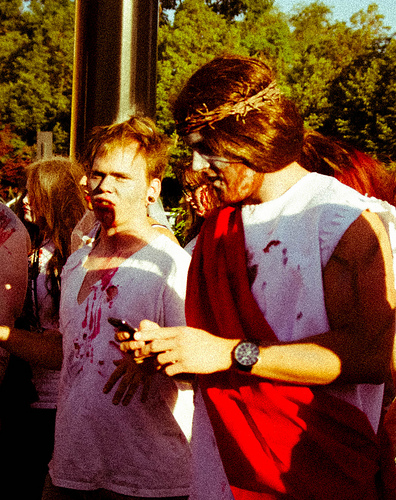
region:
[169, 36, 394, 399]
this is a person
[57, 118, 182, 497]
this is a person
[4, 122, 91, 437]
this is a person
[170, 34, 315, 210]
this is a head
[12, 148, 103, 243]
this is a head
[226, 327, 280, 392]
this is a watch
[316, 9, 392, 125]
this is green vegetation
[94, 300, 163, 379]
this is a mobile phone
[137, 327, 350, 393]
this is a hand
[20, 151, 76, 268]
THIS IS A PERSON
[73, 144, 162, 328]
THIS IS A PERSON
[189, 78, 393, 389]
THIS IS A PERSON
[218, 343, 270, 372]
THIS IS A WATCH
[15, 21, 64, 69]
THESE ARE BIG TREES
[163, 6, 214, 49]
THESE ARE BIG TREES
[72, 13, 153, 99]
THIS IS A POLE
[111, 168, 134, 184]
THIS IS AN EYE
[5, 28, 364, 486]
people covered in fake blood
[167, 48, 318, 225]
man with thorns on head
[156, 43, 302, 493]
man with watch on wrist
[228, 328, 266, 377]
a black and white watch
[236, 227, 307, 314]
blood on a shirt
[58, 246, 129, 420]
blood on a shirt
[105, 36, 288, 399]
a man looking at his cellphone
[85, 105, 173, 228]
a man with a shadow on his chin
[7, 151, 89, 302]
a woman with long hair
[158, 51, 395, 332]
a man dressed as Jesus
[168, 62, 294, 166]
man wearing crowned thorn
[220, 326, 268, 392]
man is wearing watch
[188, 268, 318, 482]
man has on red sash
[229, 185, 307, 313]
man has on blood shirt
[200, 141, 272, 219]
man has blood on face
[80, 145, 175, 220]
man has pierced ear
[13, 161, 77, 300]
woman is wearing white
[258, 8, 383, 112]
trees can be seen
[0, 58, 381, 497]
a group of people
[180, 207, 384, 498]
red sash around the body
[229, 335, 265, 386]
watch around the wrist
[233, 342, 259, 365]
face of the clock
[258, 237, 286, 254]
red spot on the fabric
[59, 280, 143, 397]
red stains on the shirt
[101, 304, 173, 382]
hand cradling a phone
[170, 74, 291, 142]
headband around the head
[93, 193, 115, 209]
mouth is slightly open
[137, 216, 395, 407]
arm is bent at the elbow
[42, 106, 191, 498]
A person is standing up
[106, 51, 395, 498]
A person is standing up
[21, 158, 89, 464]
A person is standing up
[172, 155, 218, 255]
A person is standing up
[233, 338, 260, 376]
A watch used to keep time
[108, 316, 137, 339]
A phone used for calling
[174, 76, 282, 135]
A thing to keep your hair neat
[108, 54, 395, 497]
A person on his phone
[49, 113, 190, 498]
A person with a look on his face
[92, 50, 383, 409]
man holding a phone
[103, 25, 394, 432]
man looking at a phone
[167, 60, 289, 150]
a crown of thorns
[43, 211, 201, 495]
man wearing a torn shirt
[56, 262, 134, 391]
red stains on shirt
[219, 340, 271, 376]
man wearing a wristwatch